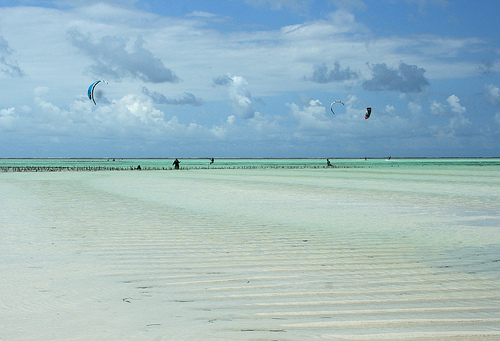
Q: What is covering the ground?
A: Sand.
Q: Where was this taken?
A: At the beach.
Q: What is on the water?
A: Ripples.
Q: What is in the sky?
A: Clouds.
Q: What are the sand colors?
A: White.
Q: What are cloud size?
A: Large.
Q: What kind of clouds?
A: Rolling.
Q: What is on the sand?
A: Ripples.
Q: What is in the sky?
A: Parasailers.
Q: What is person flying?
A: Kite.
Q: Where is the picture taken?
A: On a beach.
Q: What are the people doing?
A: Flying kites.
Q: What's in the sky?
A: Kites.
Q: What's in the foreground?
A: Sand.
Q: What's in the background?
A: Water.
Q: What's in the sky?
A: Clouds.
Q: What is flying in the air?
A: Kites.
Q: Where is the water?
A: On bottom of picture.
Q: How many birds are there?
A: None.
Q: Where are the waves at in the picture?
A: In the water.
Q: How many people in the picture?
A: Seven.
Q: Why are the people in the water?
A: They are swimming.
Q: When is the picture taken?
A: Daytime.